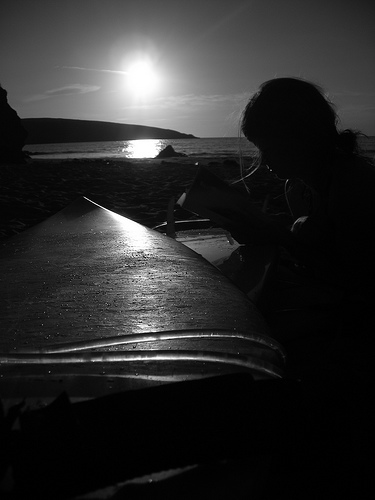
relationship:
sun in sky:
[125, 64, 155, 98] [1, 1, 373, 135]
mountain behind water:
[19, 112, 193, 141] [27, 139, 266, 157]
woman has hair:
[234, 84, 375, 351] [244, 74, 357, 162]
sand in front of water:
[33, 156, 272, 221] [27, 139, 266, 157]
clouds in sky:
[29, 82, 96, 97] [1, 1, 373, 135]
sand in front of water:
[154, 143, 192, 157] [27, 139, 266, 157]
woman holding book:
[234, 84, 375, 351] [180, 167, 260, 236]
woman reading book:
[234, 84, 375, 351] [180, 167, 260, 236]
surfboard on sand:
[9, 194, 290, 498] [33, 156, 272, 221]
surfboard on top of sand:
[9, 194, 290, 498] [154, 143, 192, 157]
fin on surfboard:
[163, 206, 183, 239] [173, 217, 246, 258]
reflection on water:
[126, 135, 161, 166] [27, 139, 266, 157]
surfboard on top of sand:
[9, 194, 290, 498] [33, 156, 272, 221]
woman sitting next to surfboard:
[234, 84, 375, 351] [9, 194, 290, 498]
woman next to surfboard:
[234, 84, 375, 351] [9, 194, 290, 498]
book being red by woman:
[180, 167, 260, 236] [234, 84, 375, 351]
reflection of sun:
[126, 135, 161, 166] [125, 64, 155, 98]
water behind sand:
[27, 139, 266, 157] [154, 143, 192, 157]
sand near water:
[154, 143, 192, 157] [27, 139, 266, 157]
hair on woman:
[244, 74, 357, 162] [234, 84, 375, 351]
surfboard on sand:
[9, 194, 290, 498] [154, 143, 192, 157]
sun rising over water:
[125, 64, 155, 98] [27, 139, 266, 157]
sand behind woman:
[154, 143, 192, 157] [234, 84, 375, 351]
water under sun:
[27, 139, 266, 157] [125, 64, 155, 98]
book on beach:
[180, 167, 260, 236] [129, 202, 322, 342]